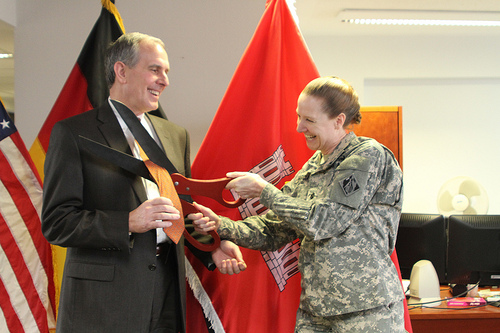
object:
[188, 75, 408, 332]
she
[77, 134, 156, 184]
blades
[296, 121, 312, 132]
nose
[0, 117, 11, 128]
star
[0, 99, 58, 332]
flag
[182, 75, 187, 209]
woman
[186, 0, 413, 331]
flag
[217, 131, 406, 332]
uniform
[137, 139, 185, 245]
orange tie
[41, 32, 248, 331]
man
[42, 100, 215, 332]
jacket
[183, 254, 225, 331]
fringe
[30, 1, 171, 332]
flag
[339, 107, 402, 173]
door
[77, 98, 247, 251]
scissors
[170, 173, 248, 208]
handles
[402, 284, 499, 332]
desk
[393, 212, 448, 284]
computer monitor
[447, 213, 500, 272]
computer monitor